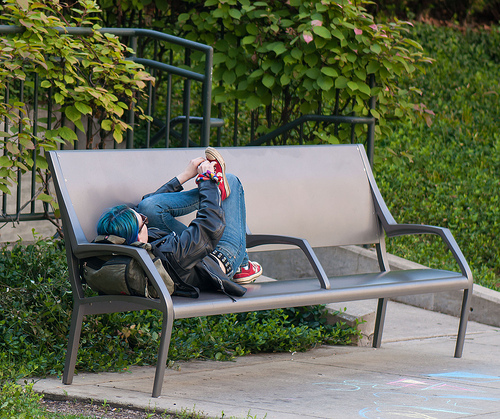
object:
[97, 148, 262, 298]
woman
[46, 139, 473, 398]
bench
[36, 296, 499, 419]
sidewalk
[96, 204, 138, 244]
hair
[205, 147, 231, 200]
shoe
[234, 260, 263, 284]
shoe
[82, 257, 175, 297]
backpack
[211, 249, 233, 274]
belt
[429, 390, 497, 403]
chalk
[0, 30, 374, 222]
staircase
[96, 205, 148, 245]
head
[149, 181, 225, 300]
leather jacket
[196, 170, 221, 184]
bracelet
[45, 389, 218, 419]
dirt patch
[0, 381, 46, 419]
grass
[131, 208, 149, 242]
face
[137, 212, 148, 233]
glasses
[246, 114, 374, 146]
hand rail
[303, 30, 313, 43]
leaf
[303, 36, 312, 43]
tip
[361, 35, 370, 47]
leaf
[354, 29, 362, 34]
tip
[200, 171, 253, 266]
blue jeans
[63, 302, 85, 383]
leg